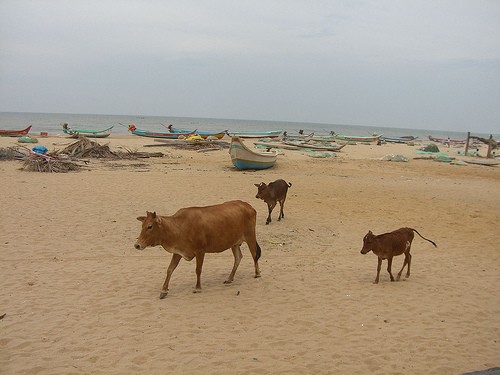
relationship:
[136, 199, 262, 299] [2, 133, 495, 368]
cow on beach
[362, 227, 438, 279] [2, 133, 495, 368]
calf on beach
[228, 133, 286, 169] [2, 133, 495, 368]
boat on beach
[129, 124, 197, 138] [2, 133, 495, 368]
boat on beach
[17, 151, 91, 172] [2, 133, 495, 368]
tree limbs are on beach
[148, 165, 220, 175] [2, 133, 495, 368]
tracks on beach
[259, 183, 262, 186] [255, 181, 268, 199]
spot on head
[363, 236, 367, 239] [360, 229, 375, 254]
spot on head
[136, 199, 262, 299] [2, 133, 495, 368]
cow walking on beach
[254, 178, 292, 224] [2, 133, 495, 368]
cow walking on beach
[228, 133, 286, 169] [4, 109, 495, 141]
boat near water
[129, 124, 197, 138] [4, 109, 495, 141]
boat near water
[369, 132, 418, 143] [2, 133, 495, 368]
boat on beach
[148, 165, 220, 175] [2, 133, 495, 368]
tracks are in beach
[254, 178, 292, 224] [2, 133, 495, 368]
cow on beach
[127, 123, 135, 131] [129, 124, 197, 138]
motor on a boat